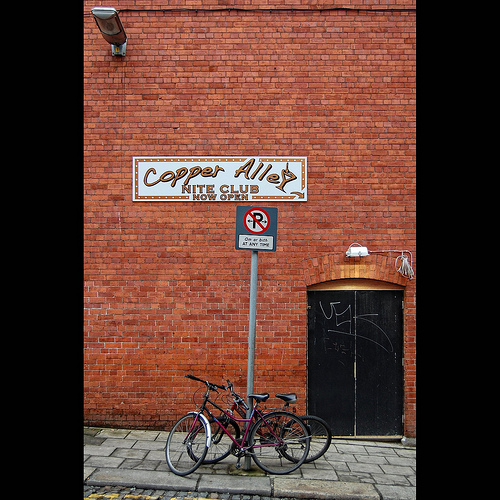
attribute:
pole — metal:
[243, 248, 259, 470]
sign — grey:
[234, 206, 279, 252]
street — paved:
[85, 485, 417, 499]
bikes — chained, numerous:
[167, 375, 333, 476]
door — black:
[306, 277, 404, 443]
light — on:
[347, 247, 370, 257]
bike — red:
[165, 374, 311, 477]